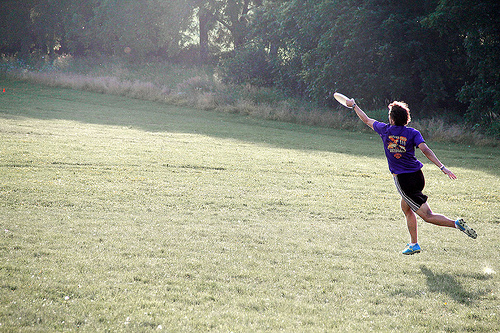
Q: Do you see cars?
A: No, there are no cars.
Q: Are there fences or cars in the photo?
A: No, there are no cars or fences.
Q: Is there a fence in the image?
A: No, there are no fences.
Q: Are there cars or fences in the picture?
A: No, there are no fences or cars.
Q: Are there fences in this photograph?
A: No, there are no fences.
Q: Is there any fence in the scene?
A: No, there are no fences.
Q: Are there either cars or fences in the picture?
A: No, there are no fences or cars.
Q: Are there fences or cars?
A: No, there are no fences or cars.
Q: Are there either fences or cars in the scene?
A: No, there are no cars or fences.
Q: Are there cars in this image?
A: No, there are no cars.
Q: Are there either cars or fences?
A: No, there are no cars or fences.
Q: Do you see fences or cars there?
A: No, there are no cars or fences.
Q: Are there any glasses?
A: No, there are no glasses.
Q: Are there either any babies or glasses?
A: No, there are no glasses or babies.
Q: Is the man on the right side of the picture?
A: Yes, the man is on the right of the image.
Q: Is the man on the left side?
A: No, the man is on the right of the image.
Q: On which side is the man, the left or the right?
A: The man is on the right of the image.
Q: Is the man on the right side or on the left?
A: The man is on the right of the image.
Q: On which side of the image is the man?
A: The man is on the right of the image.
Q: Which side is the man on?
A: The man is on the right of the image.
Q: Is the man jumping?
A: Yes, the man is jumping.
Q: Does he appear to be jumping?
A: Yes, the man is jumping.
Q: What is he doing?
A: The man is jumping.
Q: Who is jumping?
A: The man is jumping.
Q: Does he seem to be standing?
A: No, the man is jumping.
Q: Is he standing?
A: No, the man is jumping.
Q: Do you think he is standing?
A: No, the man is jumping.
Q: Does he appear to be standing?
A: No, the man is jumping.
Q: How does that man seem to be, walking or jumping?
A: The man is jumping.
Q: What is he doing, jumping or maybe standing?
A: The man is jumping.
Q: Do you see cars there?
A: No, there are no cars.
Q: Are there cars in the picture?
A: No, there are no cars.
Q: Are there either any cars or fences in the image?
A: No, there are no cars or fences.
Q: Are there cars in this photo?
A: No, there are no cars.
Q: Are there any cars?
A: No, there are no cars.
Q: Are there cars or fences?
A: No, there are no cars or fences.